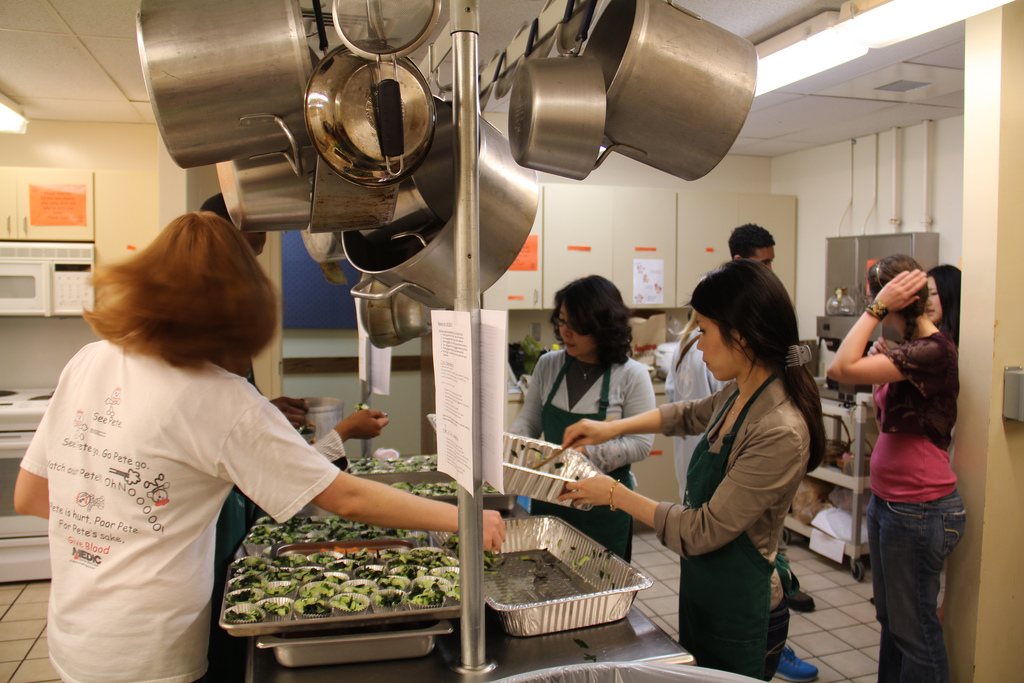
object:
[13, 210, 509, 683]
woman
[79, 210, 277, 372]
hair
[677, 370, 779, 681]
apron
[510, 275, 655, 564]
girl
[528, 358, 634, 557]
apron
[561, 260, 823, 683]
girl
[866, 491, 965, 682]
blue pants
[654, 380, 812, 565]
shirt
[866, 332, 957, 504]
shirt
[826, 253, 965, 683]
girl